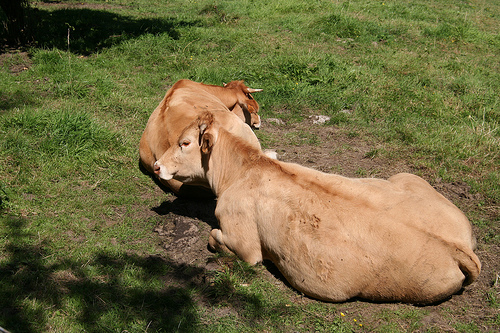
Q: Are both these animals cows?
A: Yes, all the animals are cows.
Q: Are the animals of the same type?
A: Yes, all the animals are cows.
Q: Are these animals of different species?
A: No, all the animals are cows.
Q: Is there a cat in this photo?
A: No, there are no cats.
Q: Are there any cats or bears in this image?
A: No, there are no cats or bears.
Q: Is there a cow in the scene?
A: Yes, there is a cow.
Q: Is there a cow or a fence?
A: Yes, there is a cow.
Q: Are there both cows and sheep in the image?
A: No, there is a cow but no sheep.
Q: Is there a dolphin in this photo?
A: No, there are no dolphins.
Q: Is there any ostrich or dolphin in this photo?
A: No, there are no dolphins or ostriches.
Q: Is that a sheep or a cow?
A: That is a cow.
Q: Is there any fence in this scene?
A: No, there are no fences.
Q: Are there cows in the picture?
A: Yes, there is a cow.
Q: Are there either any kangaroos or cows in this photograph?
A: Yes, there is a cow.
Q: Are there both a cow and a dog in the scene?
A: No, there is a cow but no dogs.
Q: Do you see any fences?
A: No, there are no fences.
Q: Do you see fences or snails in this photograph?
A: No, there are no fences or snails.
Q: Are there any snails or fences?
A: No, there are no fences or snails.